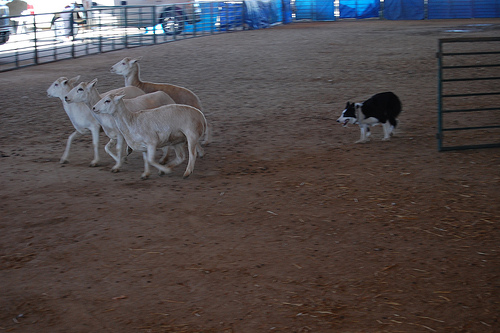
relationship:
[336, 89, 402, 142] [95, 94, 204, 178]
dog following sheep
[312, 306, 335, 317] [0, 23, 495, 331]
hay on ground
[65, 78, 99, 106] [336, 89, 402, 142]
sheep moving away from dog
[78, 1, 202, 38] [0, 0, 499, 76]
truck outside fence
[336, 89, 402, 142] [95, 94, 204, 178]
dog herding sheep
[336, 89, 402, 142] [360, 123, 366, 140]
dog has leg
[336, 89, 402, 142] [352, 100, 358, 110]
dog has ear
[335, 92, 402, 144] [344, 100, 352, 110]
dog has ear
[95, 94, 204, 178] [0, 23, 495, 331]
sheep on top of ground